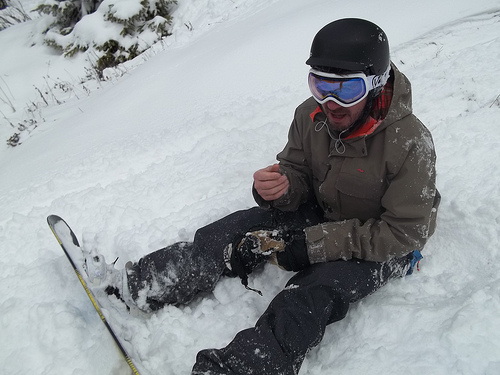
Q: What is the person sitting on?
A: Snow.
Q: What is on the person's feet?
A: Snowboard.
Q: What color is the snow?
A: White.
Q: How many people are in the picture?
A: One.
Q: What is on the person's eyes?
A: Goggles.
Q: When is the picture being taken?
A: Winter.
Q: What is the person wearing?
A: A snowsuit.